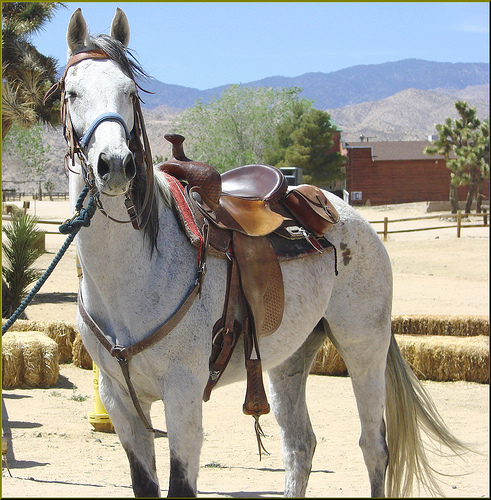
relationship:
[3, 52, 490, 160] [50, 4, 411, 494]
mountains behind horse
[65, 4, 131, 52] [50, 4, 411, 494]
ears of horse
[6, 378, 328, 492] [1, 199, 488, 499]
shadow on ground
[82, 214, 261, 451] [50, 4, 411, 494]
straps are tied on horse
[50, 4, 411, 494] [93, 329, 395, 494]
horse has legs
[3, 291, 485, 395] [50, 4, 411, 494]
hay for horse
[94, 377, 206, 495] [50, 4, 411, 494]
front legs of horse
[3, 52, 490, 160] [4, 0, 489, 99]
mountains below sky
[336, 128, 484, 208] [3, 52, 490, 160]
building in front of mountains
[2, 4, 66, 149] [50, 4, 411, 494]
palm tree beside horse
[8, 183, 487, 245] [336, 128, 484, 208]
fence in front of building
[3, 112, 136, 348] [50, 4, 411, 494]
rope tied to horse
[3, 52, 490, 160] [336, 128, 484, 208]
mountains behind building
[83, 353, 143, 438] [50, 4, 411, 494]
barrel behind horse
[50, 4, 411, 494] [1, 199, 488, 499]
horse standing on ground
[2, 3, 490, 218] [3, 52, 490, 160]
trees in front of mountains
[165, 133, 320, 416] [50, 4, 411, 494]
saddle on horse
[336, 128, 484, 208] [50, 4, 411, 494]
building behind horse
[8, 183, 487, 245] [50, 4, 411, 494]
fence behind horse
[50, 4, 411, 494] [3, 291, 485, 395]
horse surrounded by hay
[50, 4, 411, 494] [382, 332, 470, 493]
horse has a tail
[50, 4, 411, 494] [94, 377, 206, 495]
horse has front legs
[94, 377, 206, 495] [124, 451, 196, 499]
front legs have spots